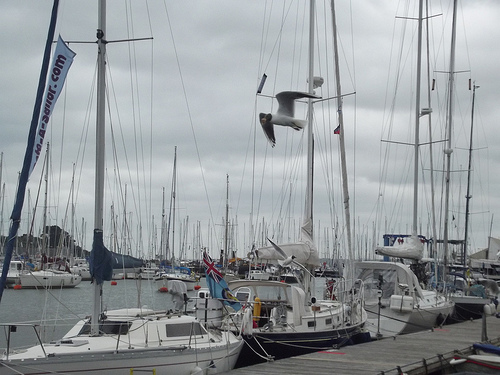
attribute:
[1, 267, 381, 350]
water — calm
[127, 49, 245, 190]
clouds — white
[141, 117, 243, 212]
clouds — white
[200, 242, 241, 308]
flag — small, red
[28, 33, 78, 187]
letters — black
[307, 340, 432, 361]
dock — wood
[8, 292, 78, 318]
water — gray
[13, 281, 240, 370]
boat — white 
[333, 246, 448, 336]
boat — white 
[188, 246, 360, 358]
boat — white 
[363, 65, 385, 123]
white clouds — white 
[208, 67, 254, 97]
blue sky — blue  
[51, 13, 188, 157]
mast — tall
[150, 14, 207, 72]
clouds — white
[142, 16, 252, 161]
clouds — white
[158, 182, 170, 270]
mast — tall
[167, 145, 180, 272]
mast — tall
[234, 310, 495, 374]
dock — gray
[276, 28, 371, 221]
mast — tall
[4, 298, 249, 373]
white boat — white 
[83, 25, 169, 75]
clouds — white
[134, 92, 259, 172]
clouds — white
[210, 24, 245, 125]
clouds — white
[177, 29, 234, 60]
clouds — white 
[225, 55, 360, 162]
bird — black, white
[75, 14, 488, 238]
clouds — white 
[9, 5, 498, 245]
clouds — white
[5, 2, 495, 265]
sky — blue 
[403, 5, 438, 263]
mast — tall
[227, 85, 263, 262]
mast — tall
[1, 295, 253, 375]
boat — white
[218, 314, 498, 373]
boardwalk — wooden